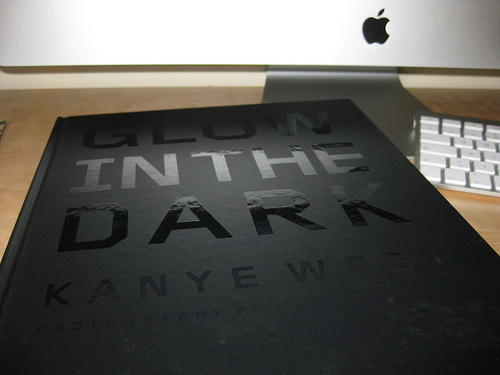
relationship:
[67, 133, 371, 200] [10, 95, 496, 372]
text of a book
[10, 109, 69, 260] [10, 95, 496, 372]
crease in book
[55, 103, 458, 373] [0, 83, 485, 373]
cover of a album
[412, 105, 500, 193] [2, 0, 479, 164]
keyboard of a computer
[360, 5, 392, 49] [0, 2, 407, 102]
logo of a computer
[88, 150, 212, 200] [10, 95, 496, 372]
light reflecting on book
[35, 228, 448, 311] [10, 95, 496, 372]
author of book